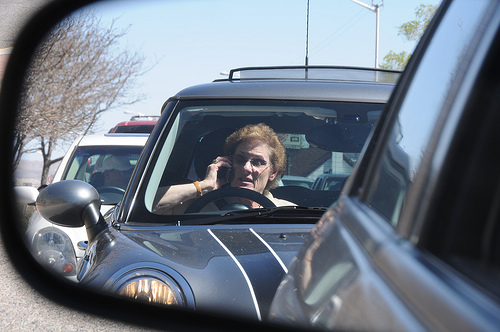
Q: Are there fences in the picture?
A: No, there are no fences.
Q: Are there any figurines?
A: No, there are no figurines.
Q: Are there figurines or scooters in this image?
A: No, there are no figurines or scooters.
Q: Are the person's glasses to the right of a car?
A: Yes, the glasses are to the right of a car.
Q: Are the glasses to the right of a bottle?
A: No, the glasses are to the right of a car.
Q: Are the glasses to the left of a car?
A: No, the glasses are to the right of a car.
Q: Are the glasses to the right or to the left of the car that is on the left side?
A: The glasses are to the right of the car.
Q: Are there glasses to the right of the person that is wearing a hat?
A: Yes, there are glasses to the right of the person.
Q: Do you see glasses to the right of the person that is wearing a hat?
A: Yes, there are glasses to the right of the person.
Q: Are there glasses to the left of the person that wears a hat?
A: No, the glasses are to the right of the person.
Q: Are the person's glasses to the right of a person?
A: Yes, the glasses are to the right of a person.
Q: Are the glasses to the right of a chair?
A: No, the glasses are to the right of a person.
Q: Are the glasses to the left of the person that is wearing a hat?
A: No, the glasses are to the right of the person.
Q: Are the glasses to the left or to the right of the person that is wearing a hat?
A: The glasses are to the right of the person.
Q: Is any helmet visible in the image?
A: No, there are no helmets.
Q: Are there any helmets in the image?
A: No, there are no helmets.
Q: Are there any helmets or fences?
A: No, there are no helmets or fences.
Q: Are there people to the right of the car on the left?
A: Yes, there is a person to the right of the car.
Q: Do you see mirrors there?
A: Yes, there is a mirror.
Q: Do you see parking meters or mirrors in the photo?
A: Yes, there is a mirror.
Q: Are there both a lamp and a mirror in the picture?
A: No, there is a mirror but no lamps.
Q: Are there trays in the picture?
A: No, there are no trays.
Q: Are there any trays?
A: No, there are no trays.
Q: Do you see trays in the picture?
A: No, there are no trays.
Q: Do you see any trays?
A: No, there are no trays.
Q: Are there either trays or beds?
A: No, there are no trays or beds.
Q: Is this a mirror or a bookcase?
A: This is a mirror.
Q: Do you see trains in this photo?
A: No, there are no trains.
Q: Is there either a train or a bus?
A: No, there are no trains or buses.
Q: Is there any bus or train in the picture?
A: No, there are no trains or buses.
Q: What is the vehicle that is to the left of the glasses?
A: The vehicle is a car.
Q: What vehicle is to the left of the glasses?
A: The vehicle is a car.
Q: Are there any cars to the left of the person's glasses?
A: Yes, there is a car to the left of the glasses.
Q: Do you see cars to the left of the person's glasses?
A: Yes, there is a car to the left of the glasses.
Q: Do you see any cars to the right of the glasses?
A: No, the car is to the left of the glasses.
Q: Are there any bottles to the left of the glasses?
A: No, there is a car to the left of the glasses.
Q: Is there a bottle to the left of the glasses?
A: No, there is a car to the left of the glasses.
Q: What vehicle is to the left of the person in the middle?
A: The vehicle is a car.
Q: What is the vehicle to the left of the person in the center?
A: The vehicle is a car.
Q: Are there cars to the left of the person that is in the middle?
A: Yes, there is a car to the left of the person.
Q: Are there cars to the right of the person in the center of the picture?
A: No, the car is to the left of the person.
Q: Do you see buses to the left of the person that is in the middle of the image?
A: No, there is a car to the left of the person.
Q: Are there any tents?
A: No, there are no tents.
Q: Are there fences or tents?
A: No, there are no tents or fences.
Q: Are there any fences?
A: No, there are no fences.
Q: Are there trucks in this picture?
A: No, there are no trucks.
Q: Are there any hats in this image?
A: Yes, there is a hat.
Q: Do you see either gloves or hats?
A: Yes, there is a hat.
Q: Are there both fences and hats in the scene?
A: No, there is a hat but no fences.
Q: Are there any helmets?
A: No, there are no helmets.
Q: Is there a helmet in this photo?
A: No, there are no helmets.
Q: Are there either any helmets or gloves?
A: No, there are no helmets or gloves.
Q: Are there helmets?
A: No, there are no helmets.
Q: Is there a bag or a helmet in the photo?
A: No, there are no helmets or bags.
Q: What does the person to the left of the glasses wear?
A: The person wears a hat.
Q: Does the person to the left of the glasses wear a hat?
A: Yes, the person wears a hat.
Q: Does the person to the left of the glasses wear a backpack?
A: No, the person wears a hat.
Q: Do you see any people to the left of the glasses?
A: Yes, there is a person to the left of the glasses.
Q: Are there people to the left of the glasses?
A: Yes, there is a person to the left of the glasses.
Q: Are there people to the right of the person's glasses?
A: No, the person is to the left of the glasses.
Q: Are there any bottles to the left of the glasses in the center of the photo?
A: No, there is a person to the left of the glasses.